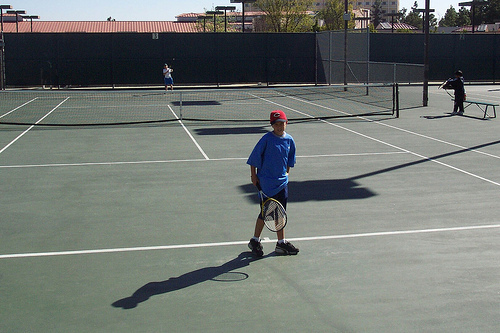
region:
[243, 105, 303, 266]
Young boy on a tennis court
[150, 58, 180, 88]
Youngster playing tennis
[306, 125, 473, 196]
Shadow cast on tennis court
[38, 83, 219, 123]
Net in the center of a tennis court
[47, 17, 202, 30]
Tiled roof top in the background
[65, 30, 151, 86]
Chain-link fence surrounding tennis court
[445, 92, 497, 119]
Park bench for spectators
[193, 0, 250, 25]
Overhead lighting on support posts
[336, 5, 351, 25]
Sign on a post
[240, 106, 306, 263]
Young boy holding a tennis racket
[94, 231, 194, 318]
white line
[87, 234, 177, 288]
white line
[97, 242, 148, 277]
white line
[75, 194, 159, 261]
white line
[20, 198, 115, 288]
white line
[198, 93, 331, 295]
young tennis player on court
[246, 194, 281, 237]
pro kennex tennis racquet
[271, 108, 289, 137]
red hat on child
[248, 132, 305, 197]
blue tshirt on boy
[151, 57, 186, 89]
tennis player in the back of court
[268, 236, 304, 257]
black shoe on boy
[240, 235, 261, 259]
black shoe on boy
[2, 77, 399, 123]
net at center court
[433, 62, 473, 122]
person near bench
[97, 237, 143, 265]
white line on court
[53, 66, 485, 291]
a tennis court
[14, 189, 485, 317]
a green and white tennis court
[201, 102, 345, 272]
a boy playing tennis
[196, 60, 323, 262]
a boy holding a tennis racket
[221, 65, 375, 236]
a boy wearing a red hat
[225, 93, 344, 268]
a boy wearing a blue shirt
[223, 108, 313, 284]
a boy wearing black sneakers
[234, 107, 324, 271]
a boy wearing white socks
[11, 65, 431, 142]
a white tennis net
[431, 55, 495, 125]
a bench on a tennis court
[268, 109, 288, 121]
red cardinal baseball hat on a young boy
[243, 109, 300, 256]
young male tennis player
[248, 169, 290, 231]
tennis racket in the young boy's hand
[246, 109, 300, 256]
young tennis player wearing a blue shirt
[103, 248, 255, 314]
young player's shadow cast on the ground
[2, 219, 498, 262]
white line going across a tennis field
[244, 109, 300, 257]
young male on a tennis court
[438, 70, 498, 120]
young male next to a green bench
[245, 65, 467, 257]
two young males on a tennis court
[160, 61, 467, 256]
three young tennis players on a tennis court